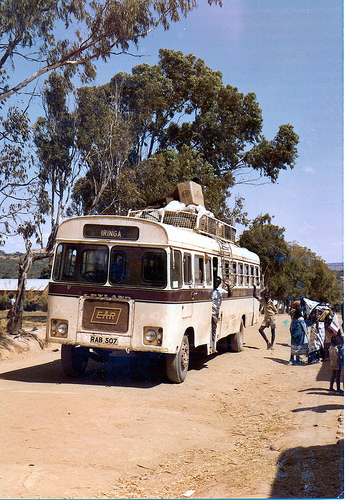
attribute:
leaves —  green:
[54, 82, 140, 160]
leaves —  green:
[322, 275, 337, 298]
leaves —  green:
[73, 48, 299, 225]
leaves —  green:
[113, 130, 135, 148]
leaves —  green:
[237, 119, 256, 134]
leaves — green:
[159, 159, 189, 173]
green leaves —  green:
[132, 165, 169, 192]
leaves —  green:
[306, 262, 315, 274]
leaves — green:
[235, 210, 290, 289]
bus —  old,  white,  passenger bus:
[142, 273, 230, 293]